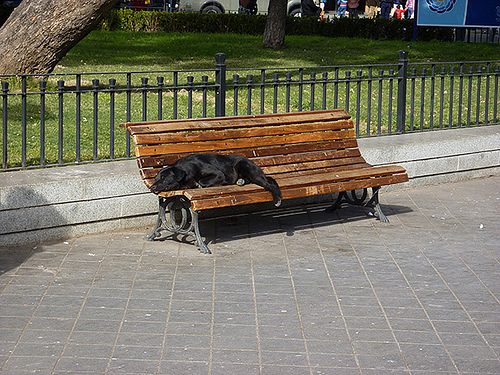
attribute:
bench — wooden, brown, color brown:
[118, 105, 409, 254]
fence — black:
[6, 65, 496, 152]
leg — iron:
[150, 202, 207, 252]